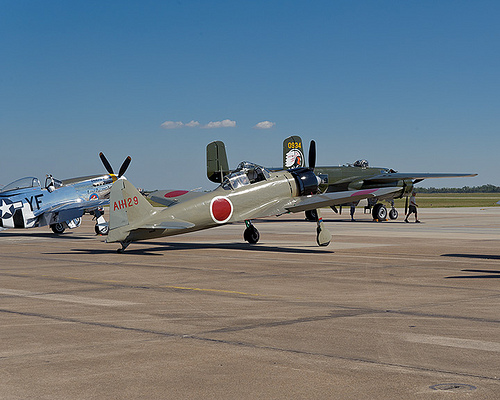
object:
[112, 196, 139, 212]
insigna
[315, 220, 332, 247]
gear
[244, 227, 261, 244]
plane wheel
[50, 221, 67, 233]
plane wheel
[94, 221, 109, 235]
plane wheel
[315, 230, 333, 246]
plane wheel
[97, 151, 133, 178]
propeller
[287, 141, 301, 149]
numbers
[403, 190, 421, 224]
man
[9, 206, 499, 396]
runway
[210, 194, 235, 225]
red circle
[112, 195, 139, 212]
numbers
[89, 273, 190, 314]
pavement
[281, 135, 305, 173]
tail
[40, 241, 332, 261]
shadow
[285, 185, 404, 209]
airplane wing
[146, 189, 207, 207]
airplane wing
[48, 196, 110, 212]
airplane wing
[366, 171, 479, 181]
airplane wing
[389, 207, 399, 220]
plane wheels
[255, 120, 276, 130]
cloud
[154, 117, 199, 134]
cloud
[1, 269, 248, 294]
stripe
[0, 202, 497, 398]
tarmac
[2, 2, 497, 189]
sky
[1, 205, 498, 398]
concrete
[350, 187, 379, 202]
stripe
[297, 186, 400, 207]
wing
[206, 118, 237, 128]
cloud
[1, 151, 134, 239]
plane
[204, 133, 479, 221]
plane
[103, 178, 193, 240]
tail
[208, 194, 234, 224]
red dot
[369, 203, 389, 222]
wheels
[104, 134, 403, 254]
airplane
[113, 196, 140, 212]
lettering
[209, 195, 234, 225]
dot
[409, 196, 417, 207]
shirt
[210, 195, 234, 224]
outline